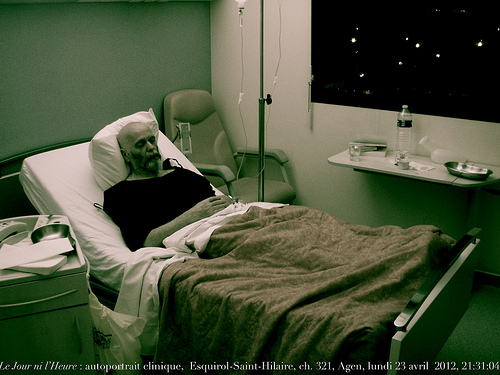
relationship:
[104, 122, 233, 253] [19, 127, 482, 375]
man in bed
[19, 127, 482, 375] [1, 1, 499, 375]
bed in hospital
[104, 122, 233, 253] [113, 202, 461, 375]
man under a blanket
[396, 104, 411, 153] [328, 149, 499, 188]
bottle on a shelf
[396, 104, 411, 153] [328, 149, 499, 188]
bottle on shelf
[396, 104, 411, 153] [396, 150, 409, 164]
bottle has water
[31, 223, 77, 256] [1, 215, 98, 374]
bed pan on table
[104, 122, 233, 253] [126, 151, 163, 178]
man has a facial hair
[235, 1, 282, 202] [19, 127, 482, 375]
tubing near bed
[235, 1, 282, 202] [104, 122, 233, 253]
tubing attached to man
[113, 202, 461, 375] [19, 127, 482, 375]
blanket on bed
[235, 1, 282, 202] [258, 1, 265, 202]
tubing hanging from a post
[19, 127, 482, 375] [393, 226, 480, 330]
bed has a rail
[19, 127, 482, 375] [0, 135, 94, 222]
bed has a headboard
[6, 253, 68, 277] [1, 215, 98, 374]
book on table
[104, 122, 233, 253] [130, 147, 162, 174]
man has facial hair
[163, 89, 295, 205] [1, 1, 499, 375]
chair in hospital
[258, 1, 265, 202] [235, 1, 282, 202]
post for tubing